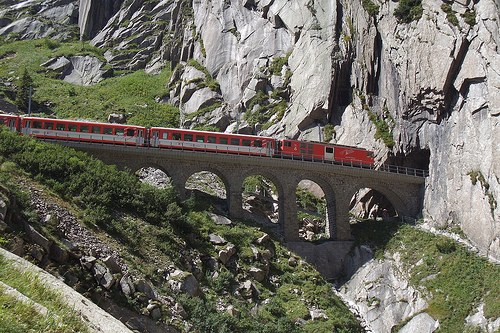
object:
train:
[0, 113, 374, 169]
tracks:
[2, 131, 430, 177]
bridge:
[36, 140, 429, 259]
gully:
[274, 236, 449, 332]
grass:
[1, 0, 499, 331]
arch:
[131, 163, 175, 193]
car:
[20, 117, 146, 148]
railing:
[10, 127, 429, 179]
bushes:
[8, 92, 175, 122]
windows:
[1, 118, 320, 157]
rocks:
[0, 0, 499, 332]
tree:
[21, 68, 36, 100]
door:
[323, 146, 335, 161]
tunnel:
[375, 140, 434, 176]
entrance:
[378, 143, 437, 179]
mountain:
[0, 0, 499, 261]